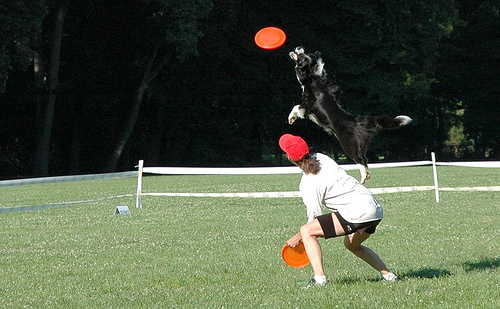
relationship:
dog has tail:
[287, 45, 413, 186] [374, 113, 412, 131]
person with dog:
[276, 133, 399, 289] [287, 45, 413, 186]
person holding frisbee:
[276, 133, 399, 289] [280, 239, 311, 268]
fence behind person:
[3, 153, 498, 218] [276, 133, 399, 289]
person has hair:
[276, 133, 399, 289] [299, 154, 321, 174]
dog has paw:
[287, 45, 413, 186] [287, 105, 299, 125]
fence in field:
[3, 153, 498, 218] [0, 162, 500, 308]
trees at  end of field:
[1, 0, 498, 180] [0, 162, 500, 308]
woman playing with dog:
[276, 133, 399, 289] [287, 45, 413, 186]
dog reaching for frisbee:
[287, 45, 413, 186] [253, 26, 286, 50]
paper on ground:
[112, 204, 128, 217] [0, 162, 500, 308]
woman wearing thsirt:
[276, 133, 399, 289] [297, 153, 383, 223]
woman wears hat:
[276, 133, 399, 289] [278, 133, 310, 160]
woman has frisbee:
[276, 133, 399, 289] [280, 239, 311, 268]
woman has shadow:
[276, 133, 399, 289] [332, 266, 454, 287]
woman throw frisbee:
[276, 133, 399, 289] [253, 26, 286, 50]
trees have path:
[1, 0, 498, 180] [431, 101, 488, 163]